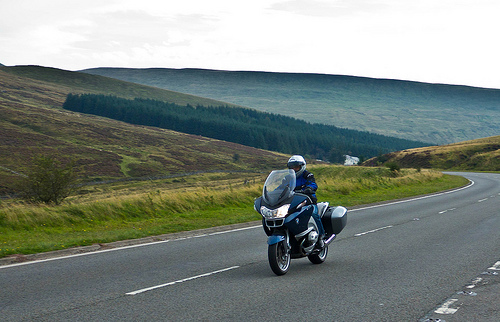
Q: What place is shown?
A: It is a field.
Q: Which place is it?
A: It is a field.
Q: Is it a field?
A: Yes, it is a field.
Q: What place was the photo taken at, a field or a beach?
A: It was taken at a field.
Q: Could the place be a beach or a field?
A: It is a field.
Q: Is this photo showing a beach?
A: No, the picture is showing a field.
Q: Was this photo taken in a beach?
A: No, the picture was taken in a field.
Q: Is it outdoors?
A: Yes, it is outdoors.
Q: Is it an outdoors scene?
A: Yes, it is outdoors.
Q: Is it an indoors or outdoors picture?
A: It is outdoors.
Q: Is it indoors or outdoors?
A: It is outdoors.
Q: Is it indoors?
A: No, it is outdoors.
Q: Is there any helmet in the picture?
A: Yes, there is a helmet.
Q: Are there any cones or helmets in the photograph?
A: Yes, there is a helmet.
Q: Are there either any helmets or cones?
A: Yes, there is a helmet.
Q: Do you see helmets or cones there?
A: Yes, there is a helmet.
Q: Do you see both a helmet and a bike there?
A: Yes, there are both a helmet and a bike.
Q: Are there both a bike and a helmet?
A: Yes, there are both a helmet and a bike.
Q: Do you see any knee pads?
A: No, there are no knee pads.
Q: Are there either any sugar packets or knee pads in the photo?
A: No, there are no knee pads or sugar packets.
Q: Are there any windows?
A: Yes, there is a window.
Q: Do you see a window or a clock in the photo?
A: Yes, there is a window.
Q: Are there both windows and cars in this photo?
A: No, there is a window but no cars.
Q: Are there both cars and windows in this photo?
A: No, there is a window but no cars.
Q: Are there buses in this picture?
A: No, there are no buses.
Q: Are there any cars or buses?
A: No, there are no buses or cars.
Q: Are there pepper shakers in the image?
A: No, there are no pepper shakers.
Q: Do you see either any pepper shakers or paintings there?
A: No, there are no pepper shakers or paintings.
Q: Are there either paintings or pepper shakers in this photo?
A: No, there are no pepper shakers or paintings.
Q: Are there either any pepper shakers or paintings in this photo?
A: No, there are no pepper shakers or paintings.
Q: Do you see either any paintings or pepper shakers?
A: No, there are no pepper shakers or paintings.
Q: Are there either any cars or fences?
A: No, there are no fences or cars.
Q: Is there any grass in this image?
A: Yes, there is grass.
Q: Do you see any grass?
A: Yes, there is grass.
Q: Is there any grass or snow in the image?
A: Yes, there is grass.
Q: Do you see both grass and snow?
A: No, there is grass but no snow.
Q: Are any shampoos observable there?
A: No, there are no shampoos.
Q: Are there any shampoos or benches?
A: No, there are no shampoos or benches.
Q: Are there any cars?
A: No, there are no cars.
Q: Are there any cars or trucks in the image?
A: No, there are no cars or trucks.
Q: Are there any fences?
A: No, there are no fences.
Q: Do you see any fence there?
A: No, there are no fences.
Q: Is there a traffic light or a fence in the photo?
A: No, there are no fences or traffic lights.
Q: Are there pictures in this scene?
A: No, there are no pictures.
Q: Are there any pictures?
A: No, there are no pictures.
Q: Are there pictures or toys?
A: No, there are no pictures or toys.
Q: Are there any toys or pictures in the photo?
A: No, there are no pictures or toys.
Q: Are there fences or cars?
A: No, there are no cars or fences.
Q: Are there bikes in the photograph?
A: Yes, there is a bike.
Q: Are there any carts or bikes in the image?
A: Yes, there is a bike.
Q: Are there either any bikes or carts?
A: Yes, there is a bike.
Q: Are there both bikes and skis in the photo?
A: No, there is a bike but no skis.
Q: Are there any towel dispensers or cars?
A: No, there are no cars or towel dispensers.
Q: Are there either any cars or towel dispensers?
A: No, there are no cars or towel dispensers.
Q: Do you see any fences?
A: No, there are no fences.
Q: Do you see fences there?
A: No, there are no fences.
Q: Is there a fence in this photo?
A: No, there are no fences.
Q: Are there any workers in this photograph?
A: No, there are no workers.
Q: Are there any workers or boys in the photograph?
A: No, there are no workers or boys.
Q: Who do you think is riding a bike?
A: The man is riding a bike.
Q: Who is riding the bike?
A: The man is riding a bike.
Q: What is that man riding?
A: The man is riding a bike.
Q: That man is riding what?
A: The man is riding a bike.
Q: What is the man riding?
A: The man is riding a bike.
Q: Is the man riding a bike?
A: Yes, the man is riding a bike.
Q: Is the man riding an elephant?
A: No, the man is riding a bike.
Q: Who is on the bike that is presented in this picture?
A: The man is on the bike.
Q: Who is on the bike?
A: The man is on the bike.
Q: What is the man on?
A: The man is on the bike.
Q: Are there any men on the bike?
A: Yes, there is a man on the bike.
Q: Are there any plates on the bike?
A: No, there is a man on the bike.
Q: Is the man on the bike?
A: Yes, the man is on the bike.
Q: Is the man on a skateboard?
A: No, the man is on the bike.